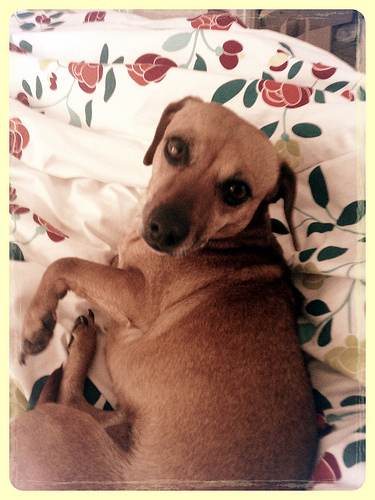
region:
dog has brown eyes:
[167, 136, 194, 167]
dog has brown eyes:
[151, 113, 201, 181]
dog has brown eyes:
[173, 121, 296, 252]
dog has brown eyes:
[165, 115, 246, 207]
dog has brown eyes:
[152, 136, 260, 233]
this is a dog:
[21, 97, 327, 474]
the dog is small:
[18, 94, 324, 455]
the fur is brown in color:
[170, 345, 217, 405]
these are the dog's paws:
[25, 301, 101, 365]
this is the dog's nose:
[146, 200, 181, 242]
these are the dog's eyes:
[163, 128, 259, 215]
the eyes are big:
[157, 127, 256, 214]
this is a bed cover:
[58, 125, 96, 182]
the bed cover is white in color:
[65, 147, 117, 189]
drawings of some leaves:
[319, 178, 366, 270]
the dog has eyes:
[114, 126, 269, 231]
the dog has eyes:
[102, 64, 244, 195]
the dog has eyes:
[161, 135, 334, 303]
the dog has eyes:
[111, 52, 319, 253]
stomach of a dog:
[150, 339, 197, 387]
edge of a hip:
[74, 406, 115, 475]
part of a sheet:
[324, 432, 348, 460]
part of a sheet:
[319, 452, 340, 480]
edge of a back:
[281, 408, 322, 463]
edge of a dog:
[68, 367, 93, 401]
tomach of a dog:
[180, 414, 211, 442]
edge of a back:
[294, 367, 320, 404]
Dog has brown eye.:
[210, 170, 264, 213]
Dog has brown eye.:
[156, 120, 246, 207]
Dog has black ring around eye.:
[214, 177, 265, 219]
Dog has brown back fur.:
[220, 375, 299, 433]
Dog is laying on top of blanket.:
[285, 373, 369, 453]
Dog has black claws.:
[67, 308, 106, 335]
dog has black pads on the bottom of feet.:
[31, 311, 57, 343]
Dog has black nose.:
[138, 208, 223, 283]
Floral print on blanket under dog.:
[135, 36, 319, 134]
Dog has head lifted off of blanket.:
[127, 80, 266, 253]